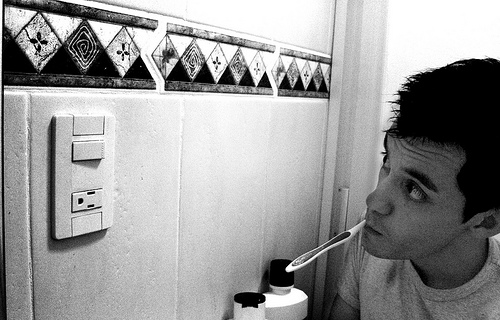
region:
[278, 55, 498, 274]
a man has a toothbrush in his mouth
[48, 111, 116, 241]
an electrical outlet is on the wall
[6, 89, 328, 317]
the wall is tiled above the sink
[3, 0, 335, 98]
a tile border is above the man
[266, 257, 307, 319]
a plastic bottle has a black lid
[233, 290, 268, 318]
a squeeze bottle is near the wall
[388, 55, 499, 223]
the boy has dark hair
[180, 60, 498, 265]
the person is looking at the wall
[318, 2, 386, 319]
a folding door is in the corner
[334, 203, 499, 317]
the man has a t-shirt on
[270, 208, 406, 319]
toothbrush is in the mouth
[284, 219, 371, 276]
toothbrush is white and black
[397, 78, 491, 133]
the hair is black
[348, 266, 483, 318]
the shirt is white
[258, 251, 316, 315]
the mouthwash is white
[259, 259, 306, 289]
the top is black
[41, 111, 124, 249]
the socket is on the wall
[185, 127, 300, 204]
the light is on the wall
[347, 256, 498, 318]
the shirt is short sleeved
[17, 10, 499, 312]
the guy is in the bathroom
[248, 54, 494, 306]
a young white man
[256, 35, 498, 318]
a guy with a toothbrush in his mouth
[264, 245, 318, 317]
a bottle of mouthwash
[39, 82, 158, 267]
the light switch is a button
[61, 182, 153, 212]
this is a power outlet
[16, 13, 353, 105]
a row of tiles in a bathroom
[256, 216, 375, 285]
the toothbrush is white with a colored grip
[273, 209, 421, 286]
the head of the toothbrush is in his mouth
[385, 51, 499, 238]
he has dark hair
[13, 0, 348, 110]
the tiles have a creative pattern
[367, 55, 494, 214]
boy has dark hair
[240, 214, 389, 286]
boy has toothbrush in mouth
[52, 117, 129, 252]
electrical outlet is light colored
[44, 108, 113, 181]
light switch on electrical outlet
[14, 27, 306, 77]
diamond patterns on tile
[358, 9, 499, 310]
boy looks at electrical outlet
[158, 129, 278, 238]
light colored tile on wall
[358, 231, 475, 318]
boy has light colored shirt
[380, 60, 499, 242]
boy has spiky hair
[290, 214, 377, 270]
two toned toothbrush in boy's mouth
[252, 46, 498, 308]
man brushing his teeth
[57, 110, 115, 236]
white socket on wall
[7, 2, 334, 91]
decorative border on wall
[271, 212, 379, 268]
toothbrush sticking out of man's mouth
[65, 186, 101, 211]
plug in on outlet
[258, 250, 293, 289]
black cap of white bottle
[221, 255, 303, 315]
two black and white bottles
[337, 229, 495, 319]
shirt of man brushing his teeth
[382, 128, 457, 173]
wrinkles on man's forehead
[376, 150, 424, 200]
eyes of man brushing his teeth